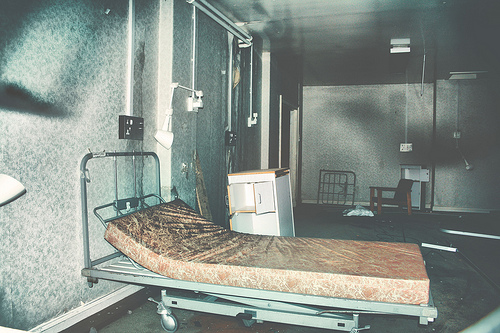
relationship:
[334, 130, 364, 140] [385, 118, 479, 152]
net on court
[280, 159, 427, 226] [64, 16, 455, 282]
furniture in room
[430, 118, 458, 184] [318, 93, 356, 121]
lamp on wall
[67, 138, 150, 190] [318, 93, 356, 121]
frame on wall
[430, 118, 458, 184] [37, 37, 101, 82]
lamp on wallpaper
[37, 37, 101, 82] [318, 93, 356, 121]
wallpaper on wall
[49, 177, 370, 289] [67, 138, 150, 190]
mattress on frame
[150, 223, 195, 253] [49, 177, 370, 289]
marks on mattress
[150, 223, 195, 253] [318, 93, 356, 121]
marks on wall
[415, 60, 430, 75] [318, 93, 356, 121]
pole on wall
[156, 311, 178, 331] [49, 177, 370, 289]
wheel on mattress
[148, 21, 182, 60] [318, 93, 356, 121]
trim on wall